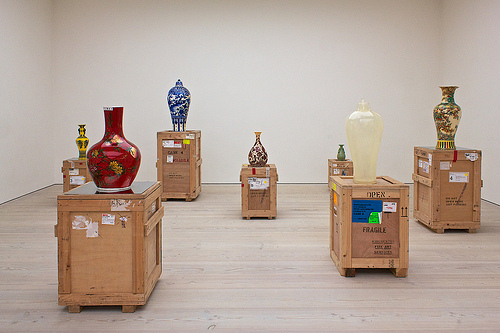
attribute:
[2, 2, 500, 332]
room — filled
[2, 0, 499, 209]
walls — white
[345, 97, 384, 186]
vase — clear, tall, white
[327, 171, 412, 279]
crate — wood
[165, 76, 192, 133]
vase — blue, white, ceramic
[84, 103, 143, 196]
vase — red, decorative, ceramic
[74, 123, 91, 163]
vase — yellow, small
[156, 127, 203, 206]
crate — wooden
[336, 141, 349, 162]
vase — green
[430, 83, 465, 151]
vase — multi colored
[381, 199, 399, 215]
label — white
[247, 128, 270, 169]
vase — beige, central to room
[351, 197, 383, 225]
label — blue, black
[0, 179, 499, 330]
floor — wood, wooden